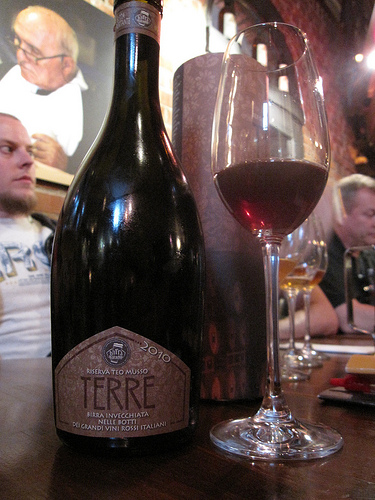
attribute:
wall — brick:
[282, 2, 373, 161]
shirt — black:
[313, 243, 373, 324]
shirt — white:
[1, 211, 52, 358]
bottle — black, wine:
[39, 4, 214, 470]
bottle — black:
[46, 0, 204, 462]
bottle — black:
[31, 23, 232, 449]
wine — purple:
[212, 160, 327, 239]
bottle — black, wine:
[3, 13, 248, 438]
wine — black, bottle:
[218, 26, 324, 467]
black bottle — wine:
[51, 0, 208, 456]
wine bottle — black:
[39, 2, 218, 447]